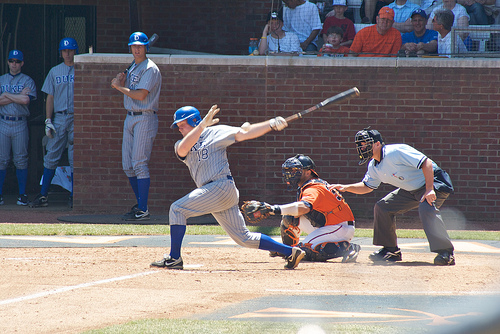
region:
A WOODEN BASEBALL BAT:
[280, 82, 365, 124]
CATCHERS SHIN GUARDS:
[302, 236, 367, 268]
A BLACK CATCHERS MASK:
[274, 151, 310, 198]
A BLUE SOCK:
[164, 213, 190, 262]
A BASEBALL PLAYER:
[150, 98, 314, 275]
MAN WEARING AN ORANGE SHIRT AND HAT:
[344, 3, 407, 61]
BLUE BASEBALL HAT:
[156, 98, 208, 135]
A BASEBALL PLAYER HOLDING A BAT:
[102, 27, 163, 225]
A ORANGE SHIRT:
[295, 176, 359, 228]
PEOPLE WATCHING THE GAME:
[245, 4, 493, 59]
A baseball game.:
[8, 16, 455, 284]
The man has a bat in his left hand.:
[150, 60, 390, 287]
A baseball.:
[230, 105, 251, 135]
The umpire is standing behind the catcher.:
[340, 125, 466, 271]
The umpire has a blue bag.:
[430, 165, 460, 195]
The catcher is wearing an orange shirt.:
[275, 151, 351, 226]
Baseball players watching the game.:
[0, 7, 176, 209]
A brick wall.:
[225, 60, 490, 150]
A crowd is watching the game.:
[240, 0, 495, 85]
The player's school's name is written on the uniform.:
[1, 78, 22, 94]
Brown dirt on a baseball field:
[14, 271, 173, 307]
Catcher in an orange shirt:
[262, 159, 383, 271]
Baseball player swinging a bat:
[151, 100, 312, 272]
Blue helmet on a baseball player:
[163, 101, 236, 148]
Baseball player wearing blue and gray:
[161, 91, 346, 264]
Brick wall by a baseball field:
[205, 74, 417, 216]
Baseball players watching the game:
[7, 44, 202, 199]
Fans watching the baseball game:
[251, 11, 450, 79]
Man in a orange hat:
[354, 7, 419, 64]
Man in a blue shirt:
[396, 7, 450, 63]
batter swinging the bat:
[158, 103, 305, 273]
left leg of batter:
[149, 178, 236, 268]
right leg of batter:
[216, 195, 303, 268]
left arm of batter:
[224, 115, 274, 147]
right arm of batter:
[170, 103, 217, 163]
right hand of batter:
[199, 101, 221, 127]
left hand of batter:
[270, 115, 287, 128]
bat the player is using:
[272, 85, 361, 126]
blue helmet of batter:
[168, 103, 207, 128]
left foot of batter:
[146, 253, 185, 270]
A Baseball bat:
[281, 80, 366, 122]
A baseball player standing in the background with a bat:
[107, 27, 164, 223]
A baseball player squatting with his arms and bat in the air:
[148, 83, 358, 276]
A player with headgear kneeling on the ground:
[245, 154, 357, 263]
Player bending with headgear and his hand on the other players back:
[328, 120, 458, 265]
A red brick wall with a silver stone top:
[74, 51, 498, 224]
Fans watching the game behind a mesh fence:
[236, 0, 499, 55]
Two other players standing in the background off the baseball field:
[1, 37, 82, 217]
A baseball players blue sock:
[166, 224, 193, 253]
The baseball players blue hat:
[171, 107, 210, 131]